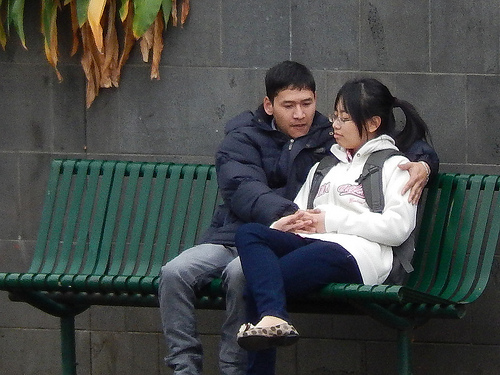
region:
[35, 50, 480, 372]
guy holding girl on green bench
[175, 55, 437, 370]
guy holding girl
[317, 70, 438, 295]
girl wearing white sweater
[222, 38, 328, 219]
guy wearing a black jacket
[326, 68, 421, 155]
girl wearing glasses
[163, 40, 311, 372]
guy wearing denim jeans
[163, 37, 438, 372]
couple holding hands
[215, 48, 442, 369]
guy arm around woman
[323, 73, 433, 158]
girl hair in pony tail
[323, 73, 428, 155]
girl wearing bangs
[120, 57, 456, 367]
A man and woman sitting on a bench.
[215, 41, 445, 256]
The man has his arms around the woman.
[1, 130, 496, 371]
The metal bench is green.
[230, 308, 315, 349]
The woman is wearing polk dot ballerina flats.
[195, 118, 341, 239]
The man is wearing a blue jacket.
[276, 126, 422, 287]
The woman is wearing a white sweat shirt.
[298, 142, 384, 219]
Two straps of a backback are visible.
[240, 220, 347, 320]
The woman is wearing dark blue jeans.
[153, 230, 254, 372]
The man is wearing light blue jeans.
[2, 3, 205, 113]
Greenish brown leaves are hanging down.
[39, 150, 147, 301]
green metal slatted bench by wall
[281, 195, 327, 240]
hands held together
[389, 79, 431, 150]
long pony tail on the girl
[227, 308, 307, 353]
polka dotted shoe on the girl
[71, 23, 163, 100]
dead leaves hanging down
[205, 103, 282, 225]
heavy dark blue jacket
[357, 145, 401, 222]
grey backpack strap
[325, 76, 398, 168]
Asian girl wearing glasses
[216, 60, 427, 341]
Asian couple sitting on a green bench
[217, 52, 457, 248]
man with his arm around a woman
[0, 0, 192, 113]
leaves hanging south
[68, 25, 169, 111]
dried out parts of the south hanging leaf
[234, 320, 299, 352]
different shades of browns and grays on a pair of flats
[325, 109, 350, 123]
metal framed corrective lenses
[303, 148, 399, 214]
dark gray straps of her backpack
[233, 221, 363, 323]
dark blue jean skinny jeans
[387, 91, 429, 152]
black, medium-long ponytail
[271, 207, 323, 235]
hands holding with male and female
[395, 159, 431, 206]
guy putting his hand around his girl friend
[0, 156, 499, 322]
dark green bench for sitting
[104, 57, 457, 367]
two people sitting on a bench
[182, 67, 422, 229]
a man and woman sitting on a bench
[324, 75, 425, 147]
a woman wearing glasses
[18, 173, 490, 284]
a green metal bench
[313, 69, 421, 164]
a woman with black hair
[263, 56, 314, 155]
a man with black hair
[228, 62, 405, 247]
a man and woman holding hands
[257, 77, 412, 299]
a woman wearing blue jeans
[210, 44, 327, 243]
a man wearing a blue jacket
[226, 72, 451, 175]
a man with his arm around a woman